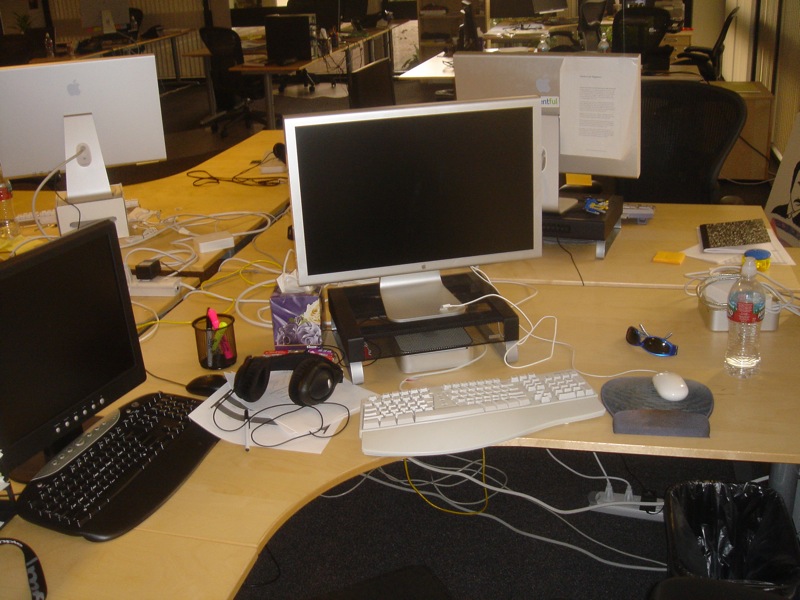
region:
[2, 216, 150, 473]
Black desktop computer monitor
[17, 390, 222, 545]
Black keyboard on desk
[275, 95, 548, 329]
Silver and black desktop computer monitor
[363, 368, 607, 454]
White keyboard on desk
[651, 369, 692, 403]
White mouse on mousepad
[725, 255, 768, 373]
Water bottle on top of desk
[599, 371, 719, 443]
Grey mousepad on top of desk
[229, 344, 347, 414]
Black headphones on top of desk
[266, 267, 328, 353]
Purple kleenex box on top of desk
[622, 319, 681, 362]
Pair of blue sunglasses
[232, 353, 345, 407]
Black pair of earphones.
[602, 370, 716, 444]
A worn grey mouse pad.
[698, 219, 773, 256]
A black and white notebook.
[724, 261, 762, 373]
Clear bottle of water with white lid.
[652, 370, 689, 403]
White mouse on a grey worn mouse pad.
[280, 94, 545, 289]
The largest front visible black screened monitor.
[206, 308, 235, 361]
A pink highlighter.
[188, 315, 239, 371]
Small black container with pink and white highlighter inside.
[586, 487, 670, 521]
A white powerstrip with two white cords and one black on it.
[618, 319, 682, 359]
Black and blue sunglasses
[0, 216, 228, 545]
Black monitor and keyboard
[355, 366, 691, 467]
White computer and mouse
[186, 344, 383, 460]
Black headset on top of paper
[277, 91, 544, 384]
Silver monitor on top of black stand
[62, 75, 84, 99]
Apple logo on monitor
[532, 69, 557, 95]
Apple logo on monitor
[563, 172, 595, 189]
Yellow post-it on monitor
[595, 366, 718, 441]
White mouse on gray pad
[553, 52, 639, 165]
Piece of paper on the monitor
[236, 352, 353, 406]
Black Sony noise cancelling headphones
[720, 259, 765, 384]
bottle of spring water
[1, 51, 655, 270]
Three apple desktop computers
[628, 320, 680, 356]
blue and black sunglasses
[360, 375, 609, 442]
White ergonomic keyboard with ten key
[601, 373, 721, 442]
mouse pad with wrist rest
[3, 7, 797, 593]
collection of work stations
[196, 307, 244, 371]
Cup for storing pens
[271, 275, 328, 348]
purple, black, yellow, and white kleenex box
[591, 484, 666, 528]
surge protector for electricity